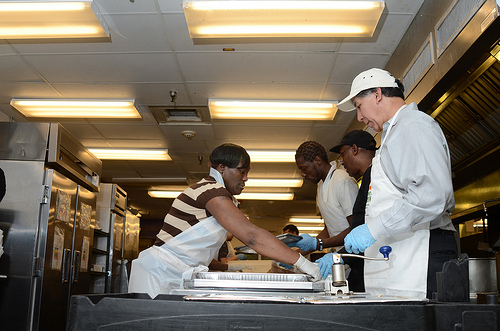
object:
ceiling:
[2, 0, 447, 200]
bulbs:
[183, 0, 391, 41]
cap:
[336, 65, 401, 112]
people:
[142, 142, 323, 296]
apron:
[362, 104, 430, 303]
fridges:
[2, 119, 109, 328]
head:
[346, 65, 412, 133]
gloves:
[313, 253, 344, 281]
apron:
[131, 214, 229, 299]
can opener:
[324, 246, 392, 297]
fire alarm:
[180, 130, 196, 142]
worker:
[292, 136, 360, 246]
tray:
[233, 233, 303, 255]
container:
[194, 270, 316, 282]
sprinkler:
[166, 87, 182, 104]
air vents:
[154, 105, 207, 124]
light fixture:
[0, 1, 113, 43]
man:
[333, 66, 468, 297]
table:
[70, 285, 470, 330]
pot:
[467, 256, 500, 296]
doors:
[40, 166, 99, 328]